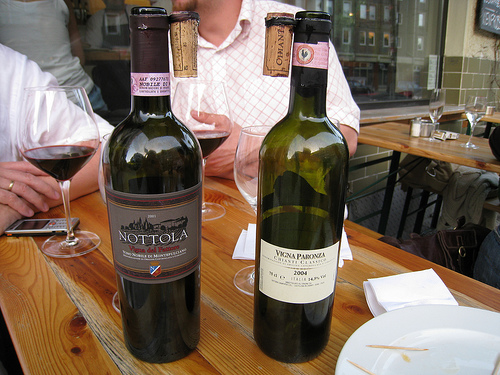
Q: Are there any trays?
A: No, there are no trays.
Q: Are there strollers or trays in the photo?
A: No, there are no trays or strollers.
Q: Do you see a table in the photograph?
A: Yes, there is a table.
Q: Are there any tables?
A: Yes, there is a table.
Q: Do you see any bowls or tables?
A: Yes, there is a table.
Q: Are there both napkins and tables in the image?
A: Yes, there are both a table and a napkin.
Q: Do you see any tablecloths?
A: No, there are no tablecloths.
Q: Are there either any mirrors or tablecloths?
A: No, there are no tablecloths or mirrors.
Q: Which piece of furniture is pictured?
A: The piece of furniture is a table.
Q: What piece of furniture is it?
A: The piece of furniture is a table.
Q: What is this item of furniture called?
A: This is a table.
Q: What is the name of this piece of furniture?
A: This is a table.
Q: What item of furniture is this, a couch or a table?
A: This is a table.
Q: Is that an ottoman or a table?
A: That is a table.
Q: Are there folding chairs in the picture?
A: No, there are no folding chairs.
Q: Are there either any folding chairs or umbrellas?
A: No, there are no folding chairs or umbrellas.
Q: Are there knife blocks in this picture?
A: No, there are no knife blocks.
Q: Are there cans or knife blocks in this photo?
A: No, there are no knife blocks or cans.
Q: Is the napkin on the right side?
A: Yes, the napkin is on the right of the image.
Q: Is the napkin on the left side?
A: No, the napkin is on the right of the image.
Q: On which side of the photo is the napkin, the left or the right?
A: The napkin is on the right of the image.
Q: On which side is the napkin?
A: The napkin is on the right of the image.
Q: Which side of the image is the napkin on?
A: The napkin is on the right of the image.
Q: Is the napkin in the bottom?
A: Yes, the napkin is in the bottom of the image.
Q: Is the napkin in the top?
A: No, the napkin is in the bottom of the image.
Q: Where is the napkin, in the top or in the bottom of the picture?
A: The napkin is in the bottom of the image.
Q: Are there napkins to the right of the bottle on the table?
A: Yes, there is a napkin to the right of the bottle.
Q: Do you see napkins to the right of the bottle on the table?
A: Yes, there is a napkin to the right of the bottle.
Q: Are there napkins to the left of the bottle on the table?
A: No, the napkin is to the right of the bottle.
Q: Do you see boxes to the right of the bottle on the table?
A: No, there is a napkin to the right of the bottle.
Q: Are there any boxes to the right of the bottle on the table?
A: No, there is a napkin to the right of the bottle.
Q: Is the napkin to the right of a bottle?
A: Yes, the napkin is to the right of a bottle.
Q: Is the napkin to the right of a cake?
A: No, the napkin is to the right of a bottle.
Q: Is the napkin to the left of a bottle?
A: No, the napkin is to the right of a bottle.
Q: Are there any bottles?
A: Yes, there is a bottle.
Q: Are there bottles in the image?
A: Yes, there is a bottle.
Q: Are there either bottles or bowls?
A: Yes, there is a bottle.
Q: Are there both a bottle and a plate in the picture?
A: Yes, there are both a bottle and a plate.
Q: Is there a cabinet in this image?
A: No, there are no cabinets.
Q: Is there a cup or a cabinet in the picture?
A: No, there are no cabinets or cups.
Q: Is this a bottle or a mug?
A: This is a bottle.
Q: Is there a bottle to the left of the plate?
A: Yes, there is a bottle to the left of the plate.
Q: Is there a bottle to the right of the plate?
A: No, the bottle is to the left of the plate.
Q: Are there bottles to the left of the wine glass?
A: Yes, there is a bottle to the left of the wine glass.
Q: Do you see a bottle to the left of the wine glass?
A: Yes, there is a bottle to the left of the wine glass.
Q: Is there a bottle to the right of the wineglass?
A: No, the bottle is to the left of the wineglass.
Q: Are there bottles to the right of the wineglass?
A: No, the bottle is to the left of the wineglass.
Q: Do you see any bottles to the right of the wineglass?
A: No, the bottle is to the left of the wineglass.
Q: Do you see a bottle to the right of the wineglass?
A: No, the bottle is to the left of the wineglass.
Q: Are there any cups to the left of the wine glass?
A: No, there is a bottle to the left of the wine glass.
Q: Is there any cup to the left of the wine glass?
A: No, there is a bottle to the left of the wine glass.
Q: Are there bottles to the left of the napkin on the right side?
A: Yes, there is a bottle to the left of the napkin.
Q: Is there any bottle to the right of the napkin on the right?
A: No, the bottle is to the left of the napkin.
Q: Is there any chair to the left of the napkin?
A: No, there is a bottle to the left of the napkin.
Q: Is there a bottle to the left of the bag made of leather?
A: Yes, there is a bottle to the left of the bag.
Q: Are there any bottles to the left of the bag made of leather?
A: Yes, there is a bottle to the left of the bag.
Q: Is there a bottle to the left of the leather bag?
A: Yes, there is a bottle to the left of the bag.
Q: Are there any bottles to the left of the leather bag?
A: Yes, there is a bottle to the left of the bag.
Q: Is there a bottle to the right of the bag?
A: No, the bottle is to the left of the bag.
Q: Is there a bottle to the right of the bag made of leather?
A: No, the bottle is to the left of the bag.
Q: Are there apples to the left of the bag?
A: No, there is a bottle to the left of the bag.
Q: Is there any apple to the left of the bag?
A: No, there is a bottle to the left of the bag.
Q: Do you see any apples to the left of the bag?
A: No, there is a bottle to the left of the bag.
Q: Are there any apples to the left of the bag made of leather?
A: No, there is a bottle to the left of the bag.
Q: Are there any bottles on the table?
A: Yes, there is a bottle on the table.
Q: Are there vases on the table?
A: No, there is a bottle on the table.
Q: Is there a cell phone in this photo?
A: Yes, there is a cell phone.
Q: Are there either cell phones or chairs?
A: Yes, there is a cell phone.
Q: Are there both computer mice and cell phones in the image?
A: No, there is a cell phone but no computer mice.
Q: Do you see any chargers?
A: No, there are no chargers.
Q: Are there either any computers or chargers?
A: No, there are no chargers or computers.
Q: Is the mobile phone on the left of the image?
A: Yes, the mobile phone is on the left of the image.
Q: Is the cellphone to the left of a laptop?
A: No, the cellphone is to the left of a bottle.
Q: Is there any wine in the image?
A: Yes, there is wine.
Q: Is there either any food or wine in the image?
A: Yes, there is wine.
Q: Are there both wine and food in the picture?
A: No, there is wine but no food.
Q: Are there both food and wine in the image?
A: No, there is wine but no food.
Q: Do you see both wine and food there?
A: No, there is wine but no food.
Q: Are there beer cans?
A: No, there are no beer cans.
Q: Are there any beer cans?
A: No, there are no beer cans.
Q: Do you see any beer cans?
A: No, there are no beer cans.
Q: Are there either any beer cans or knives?
A: No, there are no beer cans or knives.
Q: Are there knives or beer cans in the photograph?
A: No, there are no beer cans or knives.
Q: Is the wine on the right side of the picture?
A: No, the wine is on the left of the image.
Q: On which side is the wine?
A: The wine is on the left of the image.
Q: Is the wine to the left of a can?
A: No, the wine is to the left of the bottle.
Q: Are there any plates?
A: Yes, there is a plate.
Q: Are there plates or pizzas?
A: Yes, there is a plate.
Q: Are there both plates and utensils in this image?
A: No, there is a plate but no utensils.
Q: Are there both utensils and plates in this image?
A: No, there is a plate but no utensils.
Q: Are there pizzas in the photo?
A: No, there are no pizzas.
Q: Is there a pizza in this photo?
A: No, there are no pizzas.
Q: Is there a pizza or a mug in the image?
A: No, there are no pizzas or mugs.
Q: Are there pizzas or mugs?
A: No, there are no pizzas or mugs.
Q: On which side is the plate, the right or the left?
A: The plate is on the right of the image.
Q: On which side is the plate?
A: The plate is on the right of the image.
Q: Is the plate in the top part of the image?
A: No, the plate is in the bottom of the image.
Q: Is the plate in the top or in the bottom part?
A: The plate is in the bottom of the image.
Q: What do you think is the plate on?
A: The plate is on the table.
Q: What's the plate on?
A: The plate is on the table.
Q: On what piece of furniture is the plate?
A: The plate is on the table.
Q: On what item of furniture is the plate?
A: The plate is on the table.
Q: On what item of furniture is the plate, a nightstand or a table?
A: The plate is on a table.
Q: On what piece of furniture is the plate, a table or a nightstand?
A: The plate is on a table.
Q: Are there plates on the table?
A: Yes, there is a plate on the table.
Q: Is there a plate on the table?
A: Yes, there is a plate on the table.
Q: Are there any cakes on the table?
A: No, there is a plate on the table.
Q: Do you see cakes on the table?
A: No, there is a plate on the table.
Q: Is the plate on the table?
A: Yes, the plate is on the table.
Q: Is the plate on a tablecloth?
A: No, the plate is on the table.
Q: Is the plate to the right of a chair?
A: No, the plate is to the right of the bottle.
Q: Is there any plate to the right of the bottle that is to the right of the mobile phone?
A: Yes, there is a plate to the right of the bottle.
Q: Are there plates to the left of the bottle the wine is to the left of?
A: No, the plate is to the right of the bottle.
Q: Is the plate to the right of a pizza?
A: No, the plate is to the right of the bottle.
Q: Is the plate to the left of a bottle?
A: No, the plate is to the right of a bottle.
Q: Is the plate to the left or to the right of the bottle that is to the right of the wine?
A: The plate is to the right of the bottle.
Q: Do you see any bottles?
A: Yes, there is a bottle.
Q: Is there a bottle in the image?
A: Yes, there is a bottle.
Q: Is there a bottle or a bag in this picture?
A: Yes, there is a bottle.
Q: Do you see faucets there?
A: No, there are no faucets.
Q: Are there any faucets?
A: No, there are no faucets.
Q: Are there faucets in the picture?
A: No, there are no faucets.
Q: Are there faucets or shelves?
A: No, there are no faucets or shelves.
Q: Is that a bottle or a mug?
A: That is a bottle.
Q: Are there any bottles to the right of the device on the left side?
A: Yes, there is a bottle to the right of the cellphone.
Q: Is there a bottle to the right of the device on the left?
A: Yes, there is a bottle to the right of the cellphone.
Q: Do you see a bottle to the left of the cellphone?
A: No, the bottle is to the right of the cellphone.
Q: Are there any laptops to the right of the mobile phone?
A: No, there is a bottle to the right of the mobile phone.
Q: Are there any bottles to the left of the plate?
A: Yes, there is a bottle to the left of the plate.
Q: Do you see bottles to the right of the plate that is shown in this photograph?
A: No, the bottle is to the left of the plate.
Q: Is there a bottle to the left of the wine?
A: No, the bottle is to the right of the wine.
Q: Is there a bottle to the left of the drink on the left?
A: No, the bottle is to the right of the wine.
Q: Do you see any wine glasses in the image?
A: Yes, there is a wine glass.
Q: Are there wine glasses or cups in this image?
A: Yes, there is a wine glass.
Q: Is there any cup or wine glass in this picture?
A: Yes, there is a wine glass.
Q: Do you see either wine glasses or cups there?
A: Yes, there is a wine glass.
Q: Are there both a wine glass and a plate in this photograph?
A: Yes, there are both a wine glass and a plate.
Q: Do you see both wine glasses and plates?
A: Yes, there are both a wine glass and a plate.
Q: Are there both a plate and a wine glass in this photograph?
A: Yes, there are both a wine glass and a plate.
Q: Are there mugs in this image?
A: No, there are no mugs.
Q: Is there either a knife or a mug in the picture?
A: No, there are no mugs or knives.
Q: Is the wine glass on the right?
A: Yes, the wine glass is on the right of the image.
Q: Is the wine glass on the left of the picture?
A: No, the wine glass is on the right of the image.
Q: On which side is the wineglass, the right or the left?
A: The wineglass is on the right of the image.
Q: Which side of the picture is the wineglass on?
A: The wineglass is on the right of the image.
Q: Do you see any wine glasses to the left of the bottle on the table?
A: No, the wine glass is to the right of the bottle.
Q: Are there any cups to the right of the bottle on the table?
A: No, there is a wine glass to the right of the bottle.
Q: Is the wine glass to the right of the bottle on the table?
A: Yes, the wine glass is to the right of the bottle.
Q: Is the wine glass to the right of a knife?
A: No, the wine glass is to the right of the bottle.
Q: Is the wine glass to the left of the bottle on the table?
A: No, the wine glass is to the right of the bottle.